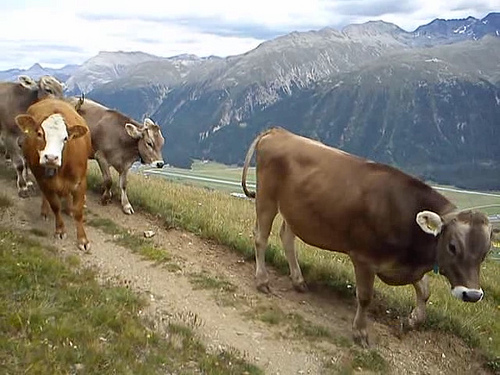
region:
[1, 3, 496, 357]
Cows standing along a mountain side.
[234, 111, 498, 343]
Brown cow with black eyes.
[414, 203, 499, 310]
Head of a cow with white inner ears and black eyes.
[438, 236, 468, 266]
Black eye of a cow.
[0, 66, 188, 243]
Three cows standing along a mountain side.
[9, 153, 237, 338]
Soiled and grass ground along a mountain side.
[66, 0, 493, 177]
Tall mountains in a rural area.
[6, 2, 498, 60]
Partly cloudy sky during the morning.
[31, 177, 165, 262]
Hooves of cows.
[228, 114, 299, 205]
Tail of a cow.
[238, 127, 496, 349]
A bovine walking on a trail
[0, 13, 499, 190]
A mountain range in the background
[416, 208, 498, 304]
Head of a bovine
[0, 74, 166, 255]
Cows walking on a path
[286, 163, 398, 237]
Brown fur on the bovine's torso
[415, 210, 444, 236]
A bovine's ear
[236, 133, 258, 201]
A tail on the back of a cow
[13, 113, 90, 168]
The head of a cow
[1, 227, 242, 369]
Patchy grass on the ground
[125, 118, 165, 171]
A cow's brown head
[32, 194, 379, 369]
Brown dirt path on a hill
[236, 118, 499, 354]
Brown cow walking on a path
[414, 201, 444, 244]
Ear on a cow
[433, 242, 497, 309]
Nose on a cow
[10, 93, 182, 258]
Two cows walking together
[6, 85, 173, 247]
Group of cows walking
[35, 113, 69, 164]
cow has a white face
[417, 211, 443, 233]
white cow ear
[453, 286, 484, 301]
white and black nose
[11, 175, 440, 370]
a dirt path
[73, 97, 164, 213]
small cow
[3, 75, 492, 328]
group of cows walking together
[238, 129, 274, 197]
cow tail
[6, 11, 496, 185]
blue mountains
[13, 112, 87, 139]
ears are sticking out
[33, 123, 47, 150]
a brown patch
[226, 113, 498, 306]
light brown cow walking path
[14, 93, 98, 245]
reddish brown cow walking path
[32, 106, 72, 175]
reddish brown cow has white face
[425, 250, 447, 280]
bell on light brown cow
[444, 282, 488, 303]
white blaze on face of light brown cow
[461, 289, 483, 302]
black nose of face of light brown cow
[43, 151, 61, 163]
white nose on face of reddish brown cow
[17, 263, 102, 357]
green grass along side path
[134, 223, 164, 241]
rock on path in front of cow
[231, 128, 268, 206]
tail on back of light brown cow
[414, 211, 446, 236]
the cow's white ear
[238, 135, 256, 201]
front cow's tail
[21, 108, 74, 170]
white face with the brown spot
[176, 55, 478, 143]
mountains in the distance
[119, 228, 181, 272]
grass separating the path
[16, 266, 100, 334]
grass on the side of the path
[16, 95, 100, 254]
brown cow in the middle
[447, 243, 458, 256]
a cow's right eye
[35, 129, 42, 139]
a cow's right eye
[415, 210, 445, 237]
a cow's right ear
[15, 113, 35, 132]
a cow's right ear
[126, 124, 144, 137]
a cow's right ear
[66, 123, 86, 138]
a cow's left ear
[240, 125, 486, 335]
brown and white cow